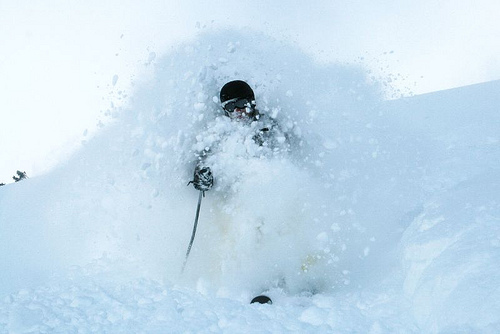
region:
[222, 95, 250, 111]
black goggles on skier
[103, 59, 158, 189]
snow flying thru air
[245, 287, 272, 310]
tip of ski in snow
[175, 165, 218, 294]
ski pole in hand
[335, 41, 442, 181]
chunks of snow kicked up by skier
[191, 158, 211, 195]
black glove on hand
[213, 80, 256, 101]
black helmet on skier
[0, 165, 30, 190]
top of tree behind hill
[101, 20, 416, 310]
snow plumes all around skier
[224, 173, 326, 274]
cloud of snow from skier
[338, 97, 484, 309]
The snow is the color white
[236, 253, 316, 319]
The person is wearing snow ski's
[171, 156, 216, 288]
The person is holding a snow stick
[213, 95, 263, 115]
The person is wearing snow goggles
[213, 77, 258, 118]
The person is wearing a hat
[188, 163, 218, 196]
The person is wearing a glove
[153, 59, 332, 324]
The person is skiing in the snow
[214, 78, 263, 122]
The head of the person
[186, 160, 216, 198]
The hand on the person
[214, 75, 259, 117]
The color of the hat is black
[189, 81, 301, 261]
skier in deep snow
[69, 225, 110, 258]
white snow on hill side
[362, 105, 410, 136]
white snow on hill side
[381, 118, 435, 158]
white snow on hill side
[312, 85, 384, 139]
white snow on hill side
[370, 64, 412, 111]
white snow on hill side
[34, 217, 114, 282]
white snow on hill side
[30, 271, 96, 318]
white snow on hill side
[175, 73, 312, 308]
skier in white snow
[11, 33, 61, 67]
white clouds n blue sky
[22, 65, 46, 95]
white clouds n blue sky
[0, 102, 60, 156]
white clouds n blue sky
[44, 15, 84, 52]
white clouds n blue sky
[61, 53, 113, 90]
white clouds n blue sky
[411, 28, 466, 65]
white clouds n blue sky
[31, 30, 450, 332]
A skier covered in snow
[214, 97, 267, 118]
A pair of black sunglasses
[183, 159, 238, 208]
A hand holding a ski pole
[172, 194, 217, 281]
A black ski pole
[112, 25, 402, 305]
A big puff of snow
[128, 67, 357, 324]
A skier covered in snow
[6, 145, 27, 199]
A tree on the left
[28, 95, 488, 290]
A ski slope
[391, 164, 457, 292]
Marks in the snow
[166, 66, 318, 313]
a man on skis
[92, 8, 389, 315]
A person skiing through show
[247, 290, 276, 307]
the tip of a ski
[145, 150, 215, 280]
a hand holdign a ski pole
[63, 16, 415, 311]
a person plowing through snow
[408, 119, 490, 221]
Large body of snow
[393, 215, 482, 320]
Large body of snow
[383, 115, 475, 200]
Large body of snow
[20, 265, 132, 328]
Large body of snow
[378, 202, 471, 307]
Large body of snow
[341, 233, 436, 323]
Large body of snow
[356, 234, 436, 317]
Large body of snow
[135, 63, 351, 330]
person in the snow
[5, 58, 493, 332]
snow in the ground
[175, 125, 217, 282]
person holding a pole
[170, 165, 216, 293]
the pole is black